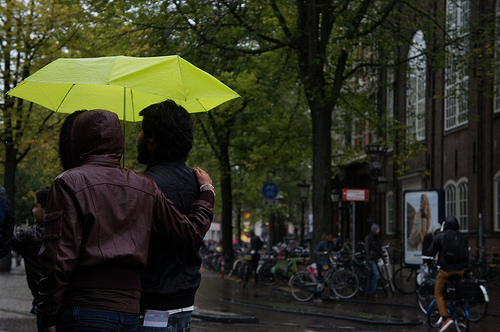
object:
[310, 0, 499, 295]
building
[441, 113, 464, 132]
windows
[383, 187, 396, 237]
windows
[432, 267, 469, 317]
brown pants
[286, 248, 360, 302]
bicycle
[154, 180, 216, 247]
arm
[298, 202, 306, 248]
pole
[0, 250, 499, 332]
ground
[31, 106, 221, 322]
leather jacket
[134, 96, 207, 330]
man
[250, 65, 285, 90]
leaves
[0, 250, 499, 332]
road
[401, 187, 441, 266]
board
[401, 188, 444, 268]
advertisement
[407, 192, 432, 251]
woman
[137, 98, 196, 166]
hair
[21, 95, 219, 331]
two people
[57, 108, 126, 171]
hood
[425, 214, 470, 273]
coat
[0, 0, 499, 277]
tree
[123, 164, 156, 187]
shoulder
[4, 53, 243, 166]
umbrella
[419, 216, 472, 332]
person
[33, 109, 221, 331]
people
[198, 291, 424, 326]
curb